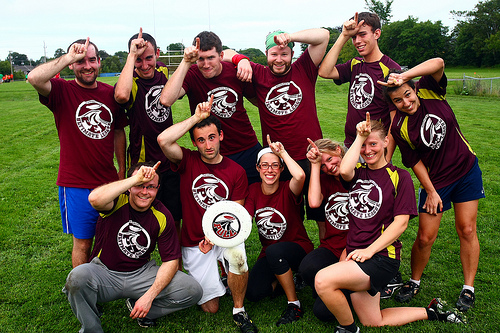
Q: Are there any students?
A: No, there are no students.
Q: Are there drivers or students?
A: No, there are no students or drivers.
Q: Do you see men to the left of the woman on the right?
A: Yes, there is a man to the left of the woman.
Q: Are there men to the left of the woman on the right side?
A: Yes, there is a man to the left of the woman.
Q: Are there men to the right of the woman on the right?
A: No, the man is to the left of the woman.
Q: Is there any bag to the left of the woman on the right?
A: No, there is a man to the left of the woman.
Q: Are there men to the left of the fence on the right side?
A: Yes, there is a man to the left of the fence.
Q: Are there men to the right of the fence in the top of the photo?
A: No, the man is to the left of the fence.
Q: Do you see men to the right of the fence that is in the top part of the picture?
A: No, the man is to the left of the fence.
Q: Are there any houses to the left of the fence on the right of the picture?
A: No, there is a man to the left of the fence.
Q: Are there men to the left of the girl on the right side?
A: Yes, there is a man to the left of the girl.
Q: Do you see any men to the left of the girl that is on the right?
A: Yes, there is a man to the left of the girl.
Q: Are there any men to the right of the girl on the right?
A: No, the man is to the left of the girl.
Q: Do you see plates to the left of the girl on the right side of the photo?
A: No, there is a man to the left of the girl.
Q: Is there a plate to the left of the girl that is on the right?
A: No, there is a man to the left of the girl.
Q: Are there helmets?
A: No, there are no helmets.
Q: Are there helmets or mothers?
A: No, there are no helmets or mothers.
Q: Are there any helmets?
A: No, there are no helmets.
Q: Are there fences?
A: Yes, there is a fence.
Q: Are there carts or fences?
A: Yes, there is a fence.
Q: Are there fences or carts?
A: Yes, there is a fence.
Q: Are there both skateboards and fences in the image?
A: No, there is a fence but no skateboards.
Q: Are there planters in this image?
A: No, there are no planters.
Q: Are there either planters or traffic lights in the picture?
A: No, there are no planters or traffic lights.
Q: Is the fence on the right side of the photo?
A: Yes, the fence is on the right of the image.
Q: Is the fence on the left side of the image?
A: No, the fence is on the right of the image.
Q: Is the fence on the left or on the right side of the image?
A: The fence is on the right of the image.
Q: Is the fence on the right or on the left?
A: The fence is on the right of the image.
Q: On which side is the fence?
A: The fence is on the right of the image.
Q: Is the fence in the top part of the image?
A: Yes, the fence is in the top of the image.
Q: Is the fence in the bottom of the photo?
A: No, the fence is in the top of the image.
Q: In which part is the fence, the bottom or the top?
A: The fence is in the top of the image.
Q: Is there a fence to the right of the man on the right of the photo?
A: Yes, there is a fence to the right of the man.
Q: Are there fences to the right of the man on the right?
A: Yes, there is a fence to the right of the man.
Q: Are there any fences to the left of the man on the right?
A: No, the fence is to the right of the man.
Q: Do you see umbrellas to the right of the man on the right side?
A: No, there is a fence to the right of the man.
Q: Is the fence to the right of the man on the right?
A: Yes, the fence is to the right of the man.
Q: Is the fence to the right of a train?
A: No, the fence is to the right of the man.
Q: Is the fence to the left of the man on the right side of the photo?
A: No, the fence is to the right of the man.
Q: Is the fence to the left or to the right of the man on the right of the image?
A: The fence is to the right of the man.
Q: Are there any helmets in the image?
A: No, there are no helmets.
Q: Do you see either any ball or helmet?
A: No, there are no helmets or balls.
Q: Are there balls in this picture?
A: No, there are no balls.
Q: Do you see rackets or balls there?
A: No, there are no balls or rackets.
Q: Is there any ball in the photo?
A: No, there are no balls.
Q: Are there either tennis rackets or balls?
A: No, there are no balls or tennis rackets.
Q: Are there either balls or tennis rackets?
A: No, there are no balls or tennis rackets.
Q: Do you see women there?
A: Yes, there is a woman.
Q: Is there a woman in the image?
A: Yes, there is a woman.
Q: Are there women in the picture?
A: Yes, there is a woman.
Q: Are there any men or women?
A: Yes, there is a woman.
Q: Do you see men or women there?
A: Yes, there is a woman.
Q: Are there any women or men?
A: Yes, there is a woman.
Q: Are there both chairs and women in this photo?
A: No, there is a woman but no chairs.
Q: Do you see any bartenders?
A: No, there are no bartenders.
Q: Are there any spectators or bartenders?
A: No, there are no bartenders or spectators.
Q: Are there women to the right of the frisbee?
A: Yes, there is a woman to the right of the frisbee.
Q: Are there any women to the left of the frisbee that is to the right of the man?
A: No, the woman is to the right of the frisbee.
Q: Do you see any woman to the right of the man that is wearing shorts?
A: Yes, there is a woman to the right of the man.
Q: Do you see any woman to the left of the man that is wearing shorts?
A: No, the woman is to the right of the man.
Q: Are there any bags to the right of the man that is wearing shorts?
A: No, there is a woman to the right of the man.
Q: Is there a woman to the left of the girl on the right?
A: Yes, there is a woman to the left of the girl.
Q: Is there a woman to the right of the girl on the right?
A: No, the woman is to the left of the girl.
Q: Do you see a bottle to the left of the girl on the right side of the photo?
A: No, there is a woman to the left of the girl.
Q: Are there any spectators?
A: No, there are no spectators.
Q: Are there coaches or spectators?
A: No, there are no spectators or coaches.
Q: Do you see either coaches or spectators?
A: No, there are no spectators or coaches.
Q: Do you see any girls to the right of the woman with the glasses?
A: Yes, there is a girl to the right of the woman.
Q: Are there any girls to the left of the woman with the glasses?
A: No, the girl is to the right of the woman.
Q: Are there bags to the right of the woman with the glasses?
A: No, there is a girl to the right of the woman.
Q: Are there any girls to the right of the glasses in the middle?
A: Yes, there is a girl to the right of the glasses.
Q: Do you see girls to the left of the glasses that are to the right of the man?
A: No, the girl is to the right of the glasses.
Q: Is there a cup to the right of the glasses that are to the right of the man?
A: No, there is a girl to the right of the glasses.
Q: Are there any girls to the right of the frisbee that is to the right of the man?
A: Yes, there is a girl to the right of the frisbee.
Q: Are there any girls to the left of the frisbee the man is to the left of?
A: No, the girl is to the right of the frisbee.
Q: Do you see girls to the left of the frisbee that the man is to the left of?
A: No, the girl is to the right of the frisbee.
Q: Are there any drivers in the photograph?
A: No, there are no drivers.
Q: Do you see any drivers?
A: No, there are no drivers.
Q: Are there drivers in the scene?
A: No, there are no drivers.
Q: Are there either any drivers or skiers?
A: No, there are no drivers or skiers.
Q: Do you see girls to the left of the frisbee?
A: No, the girl is to the right of the frisbee.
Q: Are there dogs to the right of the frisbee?
A: No, there is a girl to the right of the frisbee.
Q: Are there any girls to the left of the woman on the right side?
A: Yes, there is a girl to the left of the woman.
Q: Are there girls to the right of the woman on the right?
A: No, the girl is to the left of the woman.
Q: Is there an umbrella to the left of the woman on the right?
A: No, there is a girl to the left of the woman.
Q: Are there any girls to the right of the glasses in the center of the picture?
A: Yes, there is a girl to the right of the glasses.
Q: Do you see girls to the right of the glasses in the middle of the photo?
A: Yes, there is a girl to the right of the glasses.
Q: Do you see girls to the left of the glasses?
A: No, the girl is to the right of the glasses.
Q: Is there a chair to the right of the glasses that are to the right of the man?
A: No, there is a girl to the right of the glasses.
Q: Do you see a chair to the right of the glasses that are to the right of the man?
A: No, there is a girl to the right of the glasses.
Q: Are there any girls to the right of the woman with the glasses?
A: Yes, there is a girl to the right of the woman.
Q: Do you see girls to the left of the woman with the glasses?
A: No, the girl is to the right of the woman.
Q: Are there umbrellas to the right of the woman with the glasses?
A: No, there is a girl to the right of the woman.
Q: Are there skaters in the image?
A: No, there are no skaters.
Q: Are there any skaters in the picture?
A: No, there are no skaters.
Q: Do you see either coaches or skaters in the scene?
A: No, there are no skaters or coaches.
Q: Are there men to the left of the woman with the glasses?
A: Yes, there is a man to the left of the woman.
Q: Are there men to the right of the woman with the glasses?
A: No, the man is to the left of the woman.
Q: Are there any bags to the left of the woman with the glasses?
A: No, there is a man to the left of the woman.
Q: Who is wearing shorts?
A: The man is wearing shorts.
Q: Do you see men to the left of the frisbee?
A: Yes, there is a man to the left of the frisbee.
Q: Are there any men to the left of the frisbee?
A: Yes, there is a man to the left of the frisbee.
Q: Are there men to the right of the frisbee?
A: No, the man is to the left of the frisbee.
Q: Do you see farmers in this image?
A: No, there are no farmers.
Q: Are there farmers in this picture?
A: No, there are no farmers.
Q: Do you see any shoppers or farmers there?
A: No, there are no farmers or shoppers.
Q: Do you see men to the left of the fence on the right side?
A: Yes, there is a man to the left of the fence.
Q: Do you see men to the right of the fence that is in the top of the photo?
A: No, the man is to the left of the fence.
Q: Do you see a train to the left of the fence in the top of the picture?
A: No, there is a man to the left of the fence.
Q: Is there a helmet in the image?
A: No, there are no helmets.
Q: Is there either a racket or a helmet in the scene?
A: No, there are no helmets or rackets.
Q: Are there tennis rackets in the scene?
A: No, there are no tennis rackets.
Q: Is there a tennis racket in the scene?
A: No, there are no rackets.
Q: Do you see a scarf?
A: Yes, there is a scarf.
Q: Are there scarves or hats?
A: Yes, there is a scarf.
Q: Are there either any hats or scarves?
A: Yes, there is a scarf.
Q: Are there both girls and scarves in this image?
A: Yes, there are both a scarf and a girl.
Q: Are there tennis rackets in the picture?
A: No, there are no tennis rackets.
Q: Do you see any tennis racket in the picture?
A: No, there are no rackets.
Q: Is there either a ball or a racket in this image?
A: No, there are no rackets or balls.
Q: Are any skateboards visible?
A: No, there are no skateboards.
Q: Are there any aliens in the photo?
A: No, there are no aliens.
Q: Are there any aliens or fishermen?
A: No, there are no aliens or fishermen.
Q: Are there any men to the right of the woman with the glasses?
A: No, the man is to the left of the woman.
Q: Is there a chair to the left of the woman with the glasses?
A: No, there is a man to the left of the woman.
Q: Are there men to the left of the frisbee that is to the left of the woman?
A: Yes, there is a man to the left of the frisbee.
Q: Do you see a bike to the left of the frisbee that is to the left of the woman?
A: No, there is a man to the left of the frisbee.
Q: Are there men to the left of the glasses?
A: Yes, there is a man to the left of the glasses.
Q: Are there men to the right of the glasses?
A: No, the man is to the left of the glasses.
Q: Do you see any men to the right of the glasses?
A: No, the man is to the left of the glasses.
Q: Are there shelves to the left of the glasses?
A: No, there is a man to the left of the glasses.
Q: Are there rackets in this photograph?
A: No, there are no rackets.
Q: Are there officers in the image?
A: No, there are no officers.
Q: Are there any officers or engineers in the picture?
A: No, there are no officers or engineers.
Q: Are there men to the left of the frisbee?
A: Yes, there is a man to the left of the frisbee.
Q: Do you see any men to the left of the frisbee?
A: Yes, there is a man to the left of the frisbee.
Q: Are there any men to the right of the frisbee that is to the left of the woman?
A: No, the man is to the left of the frisbee.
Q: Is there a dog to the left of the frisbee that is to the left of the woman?
A: No, there is a man to the left of the frisbee.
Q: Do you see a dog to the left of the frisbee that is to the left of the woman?
A: No, there is a man to the left of the frisbee.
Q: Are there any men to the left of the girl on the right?
A: Yes, there is a man to the left of the girl.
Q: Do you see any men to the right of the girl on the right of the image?
A: No, the man is to the left of the girl.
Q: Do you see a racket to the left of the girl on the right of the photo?
A: No, there is a man to the left of the girl.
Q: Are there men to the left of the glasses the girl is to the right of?
A: Yes, there is a man to the left of the glasses.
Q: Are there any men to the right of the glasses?
A: No, the man is to the left of the glasses.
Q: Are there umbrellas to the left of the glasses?
A: No, there is a man to the left of the glasses.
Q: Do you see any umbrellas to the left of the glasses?
A: No, there is a man to the left of the glasses.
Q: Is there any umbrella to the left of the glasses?
A: No, there is a man to the left of the glasses.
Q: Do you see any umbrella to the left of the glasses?
A: No, there is a man to the left of the glasses.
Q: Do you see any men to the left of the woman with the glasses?
A: Yes, there is a man to the left of the woman.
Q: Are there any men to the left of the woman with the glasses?
A: Yes, there is a man to the left of the woman.